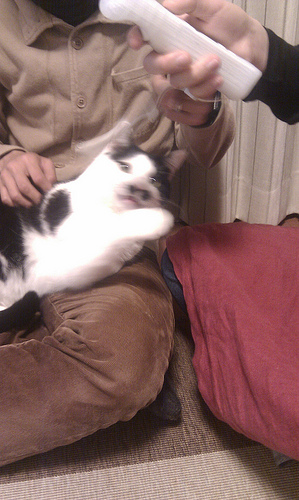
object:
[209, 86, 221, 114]
watch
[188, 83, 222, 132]
wrist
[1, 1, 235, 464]
person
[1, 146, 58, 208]
hand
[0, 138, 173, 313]
cat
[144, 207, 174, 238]
paw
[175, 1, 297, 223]
curtain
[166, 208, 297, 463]
shirt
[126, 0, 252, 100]
hand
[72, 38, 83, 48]
button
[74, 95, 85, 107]
button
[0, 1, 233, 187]
shirt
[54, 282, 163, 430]
lap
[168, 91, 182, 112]
ring